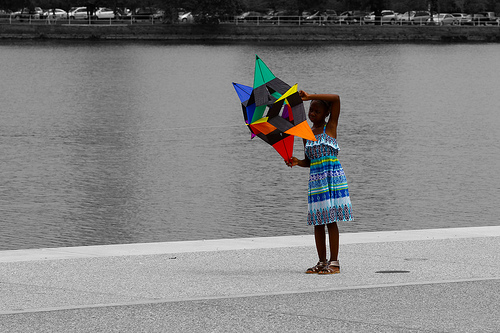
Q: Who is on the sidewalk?
A: A girl.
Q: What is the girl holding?
A: A kite.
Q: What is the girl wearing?
A: The girl is wearing a sundress.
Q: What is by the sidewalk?
A: Water is by the sidewalk.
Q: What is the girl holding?
A: A kite.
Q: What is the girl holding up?
A: A kite.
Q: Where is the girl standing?
A: On the sidewalk next to the water.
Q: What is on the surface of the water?
A: Ripples are on the surface of the water.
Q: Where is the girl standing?
A: On the sidewalk by the water.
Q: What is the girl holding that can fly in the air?
A: A kite.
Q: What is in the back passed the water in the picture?
A: A parking lot that cars are parked in.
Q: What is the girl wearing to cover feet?
A: The girl is wearing sandals to cover feet.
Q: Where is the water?
A: Next to the sidewalk.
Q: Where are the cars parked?
A: On the other side of the water.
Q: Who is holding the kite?
A: The little girl.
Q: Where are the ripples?
A: In the water.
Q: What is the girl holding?
A: The kite.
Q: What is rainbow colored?
A: The kite.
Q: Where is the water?
A: Behind the girl.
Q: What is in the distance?
A: Cars.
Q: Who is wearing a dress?
A: The girl.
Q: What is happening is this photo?
A: A girl holding a kit.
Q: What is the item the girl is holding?
A: A kite.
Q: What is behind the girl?
A: Water.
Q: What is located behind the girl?
A: A body of water.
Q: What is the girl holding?
A: A kite.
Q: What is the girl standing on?
A: The concrete.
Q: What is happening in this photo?
A: A girl is holding a kite.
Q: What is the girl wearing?
A: A dress.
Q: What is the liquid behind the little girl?
A: Water.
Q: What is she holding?
A: Kite.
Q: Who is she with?
A: No one.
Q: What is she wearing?
A: Sandals.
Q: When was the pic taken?
A: During the day.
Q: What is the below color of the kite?
A: Orange.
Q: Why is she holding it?
A: Display.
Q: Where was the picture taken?
A: At the lake.